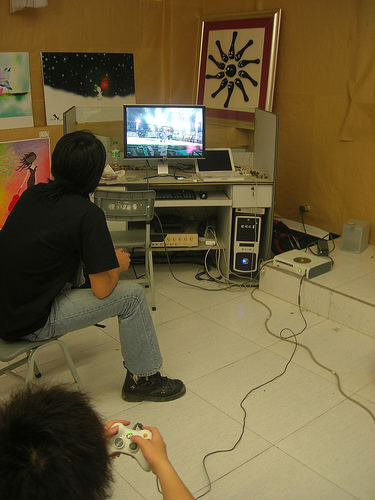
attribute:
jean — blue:
[29, 275, 173, 376]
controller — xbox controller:
[101, 419, 152, 470]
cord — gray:
[132, 262, 311, 497]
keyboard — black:
[137, 183, 195, 199]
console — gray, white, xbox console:
[266, 240, 335, 279]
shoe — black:
[116, 364, 187, 404]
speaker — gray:
[340, 217, 371, 253]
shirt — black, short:
[0, 181, 121, 341]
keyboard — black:
[112, 159, 227, 207]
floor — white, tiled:
[191, 298, 313, 456]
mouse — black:
[199, 191, 207, 200]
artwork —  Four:
[194, 7, 282, 130]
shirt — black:
[8, 188, 124, 273]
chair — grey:
[108, 209, 200, 286]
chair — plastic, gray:
[74, 187, 159, 309]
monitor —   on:
[123, 106, 205, 160]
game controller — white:
[100, 410, 162, 466]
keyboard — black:
[136, 188, 199, 204]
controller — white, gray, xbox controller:
[96, 417, 162, 472]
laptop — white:
[193, 146, 245, 182]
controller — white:
[103, 421, 152, 473]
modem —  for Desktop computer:
[228, 212, 261, 278]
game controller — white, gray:
[106, 421, 154, 471]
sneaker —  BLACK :
[125, 367, 186, 399]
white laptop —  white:
[195, 146, 242, 186]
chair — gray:
[90, 188, 163, 311]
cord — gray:
[226, 376, 276, 462]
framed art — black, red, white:
[190, 18, 278, 126]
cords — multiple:
[197, 221, 261, 284]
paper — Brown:
[272, 4, 372, 228]